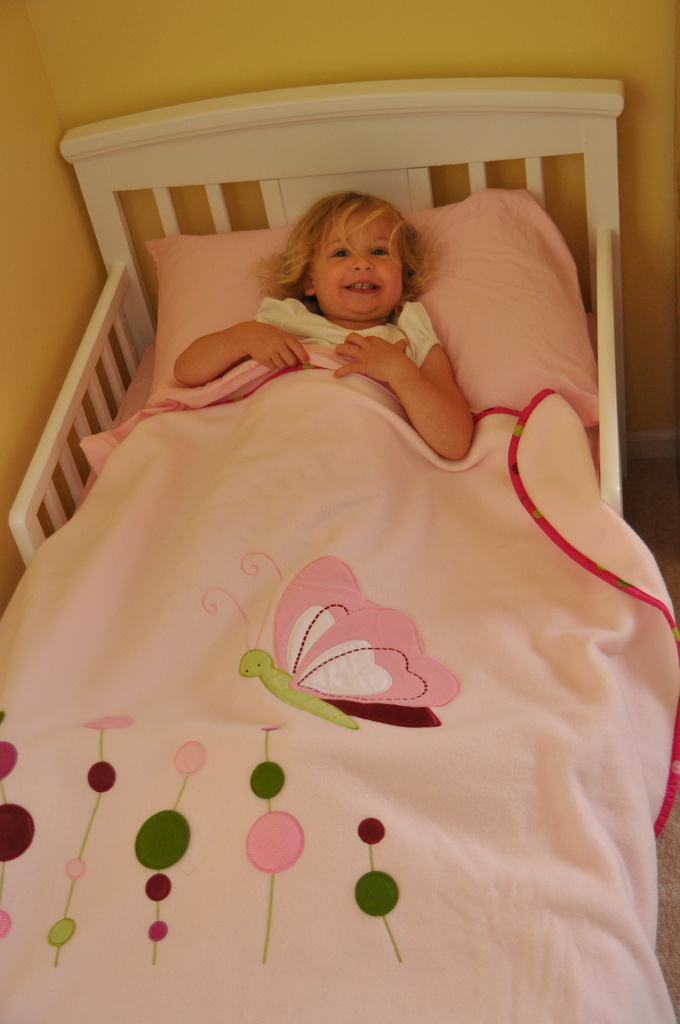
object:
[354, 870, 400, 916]
design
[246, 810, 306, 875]
design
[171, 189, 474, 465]
child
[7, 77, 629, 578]
bed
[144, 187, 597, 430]
pillow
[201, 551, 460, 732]
butterfly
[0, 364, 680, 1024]
blanket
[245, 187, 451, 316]
hair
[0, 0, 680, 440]
wall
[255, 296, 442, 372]
shirt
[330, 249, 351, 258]
eye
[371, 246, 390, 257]
eye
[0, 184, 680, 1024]
bed